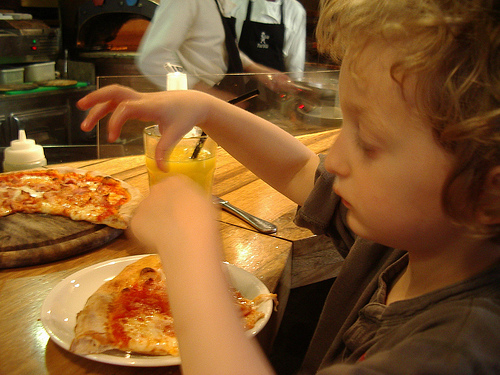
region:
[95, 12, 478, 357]
young boy wearing brown shirt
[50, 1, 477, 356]
young boy eating pizza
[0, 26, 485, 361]
young boy at restaurant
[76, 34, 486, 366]
young boy sitting at table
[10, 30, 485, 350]
young boy with orange juice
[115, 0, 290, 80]
two people working at restaurant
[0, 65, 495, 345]
young boy with whole pizza in front of him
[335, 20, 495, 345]
young boy with curly brown hair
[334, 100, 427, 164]
the eye of a boy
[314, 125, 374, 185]
the nose of a boy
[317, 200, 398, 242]
the chin of a boy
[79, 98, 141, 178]
the finger of a boy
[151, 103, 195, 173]
the thumb of a boy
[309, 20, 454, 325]
a boy wearing a shirt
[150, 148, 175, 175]
his finger is in the liquid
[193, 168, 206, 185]
the liquid is yellow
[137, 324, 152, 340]
the cheese is white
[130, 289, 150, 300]
the sauce is red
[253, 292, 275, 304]
the cheese is stringy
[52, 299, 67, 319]
the plate is white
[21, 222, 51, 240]
the board is dark brown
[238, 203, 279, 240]
the utencil is silver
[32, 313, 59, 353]
the plate is on the table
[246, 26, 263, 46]
the apron is black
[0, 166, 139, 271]
most of a pizza on a wooden dish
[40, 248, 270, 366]
large piece of pizza on a plate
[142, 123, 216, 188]
top part of a glass with orange liquid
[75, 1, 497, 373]
small child near table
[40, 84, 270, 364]
boy's hands are over pizza dish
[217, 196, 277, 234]
heavy handle of a utensil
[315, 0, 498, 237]
child's hair is in loose brown curls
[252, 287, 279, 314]
cheese going over edge of plate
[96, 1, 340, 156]
two people behind a glass partition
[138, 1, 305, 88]
people are wearing white shirts and black aprons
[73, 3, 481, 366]
a young boy with blonde hair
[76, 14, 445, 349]
a boy eating pizza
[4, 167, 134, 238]
a small cheese pizza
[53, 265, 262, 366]
a slice of cheese pizza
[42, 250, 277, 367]
a slice of pizza on a white plate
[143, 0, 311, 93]
two pizza chefs wearing black and white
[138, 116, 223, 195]
a glass of orange juice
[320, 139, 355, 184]
the nose of a boy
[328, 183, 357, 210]
the mouth of a boy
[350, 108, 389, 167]
the eye of a boy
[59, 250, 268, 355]
pizza on a kid's plate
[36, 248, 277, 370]
white plate on the counter